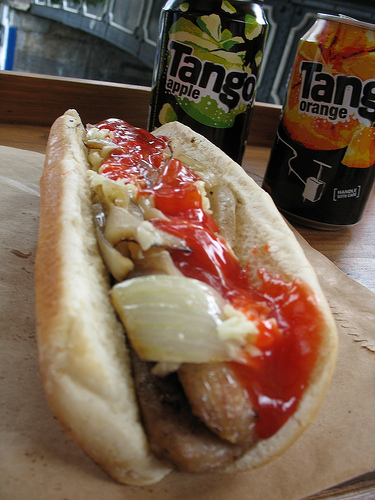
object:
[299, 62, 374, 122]
tango orange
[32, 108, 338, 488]
hotdog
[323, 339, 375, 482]
napkin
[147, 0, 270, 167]
can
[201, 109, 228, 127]
colors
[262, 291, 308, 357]
sauce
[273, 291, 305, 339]
sauce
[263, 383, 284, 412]
sauce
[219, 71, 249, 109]
letter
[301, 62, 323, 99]
letter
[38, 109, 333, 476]
dog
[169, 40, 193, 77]
letter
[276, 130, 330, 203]
cartoon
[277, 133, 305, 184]
wire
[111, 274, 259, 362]
onion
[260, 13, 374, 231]
can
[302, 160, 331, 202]
detonator